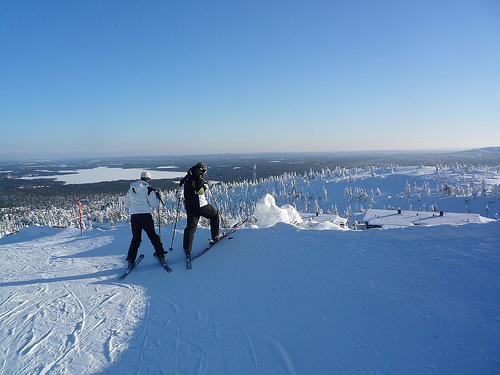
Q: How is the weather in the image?
A: It is clear.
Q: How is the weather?
A: It is clear.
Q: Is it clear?
A: Yes, it is clear.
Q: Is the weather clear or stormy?
A: It is clear.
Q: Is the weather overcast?
A: No, it is clear.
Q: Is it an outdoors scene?
A: Yes, it is outdoors.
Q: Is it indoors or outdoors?
A: It is outdoors.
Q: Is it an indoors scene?
A: No, it is outdoors.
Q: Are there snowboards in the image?
A: No, there are no snowboards.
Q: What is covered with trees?
A: The mountain is covered with trees.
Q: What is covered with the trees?
A: The mountain is covered with trees.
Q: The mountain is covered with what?
A: The mountain is covered with trees.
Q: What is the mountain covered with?
A: The mountain is covered with trees.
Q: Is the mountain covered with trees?
A: Yes, the mountain is covered with trees.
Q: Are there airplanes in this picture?
A: No, there are no airplanes.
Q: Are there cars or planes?
A: No, there are no planes or cars.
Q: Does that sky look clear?
A: Yes, the sky is clear.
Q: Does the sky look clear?
A: Yes, the sky is clear.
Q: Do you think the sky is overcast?
A: No, the sky is clear.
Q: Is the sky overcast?
A: No, the sky is clear.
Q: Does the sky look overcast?
A: No, the sky is clear.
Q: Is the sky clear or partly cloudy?
A: The sky is clear.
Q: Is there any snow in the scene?
A: Yes, there is snow.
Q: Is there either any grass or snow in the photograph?
A: Yes, there is snow.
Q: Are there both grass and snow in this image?
A: No, there is snow but no grass.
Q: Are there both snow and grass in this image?
A: No, there is snow but no grass.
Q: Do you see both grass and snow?
A: No, there is snow but no grass.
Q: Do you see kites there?
A: No, there are no kites.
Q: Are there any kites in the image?
A: No, there are no kites.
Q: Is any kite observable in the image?
A: No, there are no kites.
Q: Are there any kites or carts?
A: No, there are no kites or carts.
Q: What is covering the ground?
A: The snow is covering the ground.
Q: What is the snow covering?
A: The snow is covering the ground.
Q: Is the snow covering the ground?
A: Yes, the snow is covering the ground.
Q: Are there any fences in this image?
A: No, there are no fences.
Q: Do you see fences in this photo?
A: No, there are no fences.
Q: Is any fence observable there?
A: No, there are no fences.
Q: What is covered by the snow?
A: The ground is covered by the snow.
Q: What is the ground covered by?
A: The ground is covered by the snow.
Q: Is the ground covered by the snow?
A: Yes, the ground is covered by the snow.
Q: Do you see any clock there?
A: No, there are no clocks.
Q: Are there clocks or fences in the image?
A: No, there are no clocks or fences.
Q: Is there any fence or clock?
A: No, there are no clocks or fences.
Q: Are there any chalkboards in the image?
A: No, there are no chalkboards.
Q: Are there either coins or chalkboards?
A: No, there are no chalkboards or coins.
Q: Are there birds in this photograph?
A: No, there are no birds.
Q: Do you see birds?
A: No, there are no birds.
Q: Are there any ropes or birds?
A: No, there are no birds or ropes.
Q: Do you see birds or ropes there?
A: No, there are no birds or ropes.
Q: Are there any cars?
A: No, there are no cars.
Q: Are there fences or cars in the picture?
A: No, there are no cars or fences.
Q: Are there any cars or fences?
A: No, there are no cars or fences.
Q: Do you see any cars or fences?
A: No, there are no cars or fences.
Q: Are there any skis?
A: Yes, there are skis.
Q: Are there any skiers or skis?
A: Yes, there are skis.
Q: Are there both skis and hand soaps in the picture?
A: No, there are skis but no hand soaps.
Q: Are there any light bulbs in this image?
A: No, there are no light bulbs.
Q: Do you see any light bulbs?
A: No, there are no light bulbs.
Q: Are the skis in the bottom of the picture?
A: Yes, the skis are in the bottom of the image.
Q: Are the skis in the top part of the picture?
A: No, the skis are in the bottom of the image.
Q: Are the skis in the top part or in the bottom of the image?
A: The skis are in the bottom of the image.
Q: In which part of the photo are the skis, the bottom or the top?
A: The skis are in the bottom of the image.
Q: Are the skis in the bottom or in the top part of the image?
A: The skis are in the bottom of the image.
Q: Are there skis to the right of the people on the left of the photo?
A: Yes, there are skis to the right of the people.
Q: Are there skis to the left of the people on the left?
A: No, the skis are to the right of the people.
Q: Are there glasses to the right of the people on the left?
A: No, there are skis to the right of the people.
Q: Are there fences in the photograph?
A: No, there are no fences.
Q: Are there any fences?
A: No, there are no fences.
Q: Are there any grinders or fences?
A: No, there are no fences or grinders.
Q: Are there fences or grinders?
A: No, there are no fences or grinders.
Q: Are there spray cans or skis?
A: Yes, there are skis.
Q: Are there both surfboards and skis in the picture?
A: No, there are skis but no surfboards.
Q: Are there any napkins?
A: No, there are no napkins.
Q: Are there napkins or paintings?
A: No, there are no napkins or paintings.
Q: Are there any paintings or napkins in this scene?
A: No, there are no napkins or paintings.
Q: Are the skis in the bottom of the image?
A: Yes, the skis are in the bottom of the image.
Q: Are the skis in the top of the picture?
A: No, the skis are in the bottom of the image.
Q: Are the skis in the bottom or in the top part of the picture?
A: The skis are in the bottom of the image.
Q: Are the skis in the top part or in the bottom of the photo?
A: The skis are in the bottom of the image.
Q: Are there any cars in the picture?
A: No, there are no cars.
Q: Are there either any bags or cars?
A: No, there are no cars or bags.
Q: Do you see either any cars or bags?
A: No, there are no cars or bags.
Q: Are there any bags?
A: No, there are no bags.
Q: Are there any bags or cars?
A: No, there are no bags or cars.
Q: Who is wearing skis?
A: The people are wearing skis.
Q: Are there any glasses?
A: No, there are no glasses.